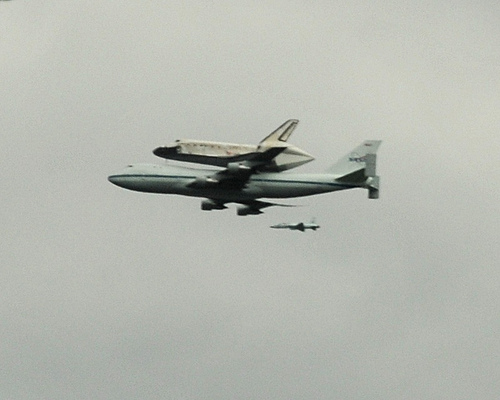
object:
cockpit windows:
[126, 163, 135, 171]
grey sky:
[53, 233, 465, 375]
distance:
[1, 2, 482, 397]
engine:
[225, 158, 259, 172]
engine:
[192, 172, 224, 187]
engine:
[197, 193, 229, 211]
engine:
[232, 203, 263, 215]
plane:
[105, 137, 383, 216]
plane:
[269, 220, 321, 233]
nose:
[105, 170, 120, 184]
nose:
[152, 144, 180, 159]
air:
[1, 1, 500, 399]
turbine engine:
[200, 196, 230, 212]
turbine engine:
[236, 201, 264, 216]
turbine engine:
[222, 156, 258, 174]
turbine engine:
[191, 173, 222, 186]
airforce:
[265, 222, 319, 236]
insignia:
[347, 148, 368, 167]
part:
[266, 116, 292, 144]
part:
[335, 146, 399, 204]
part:
[277, 142, 306, 171]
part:
[106, 165, 205, 201]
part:
[260, 170, 341, 202]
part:
[266, 222, 316, 235]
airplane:
[107, 139, 383, 218]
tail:
[322, 137, 383, 197]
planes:
[150, 119, 319, 173]